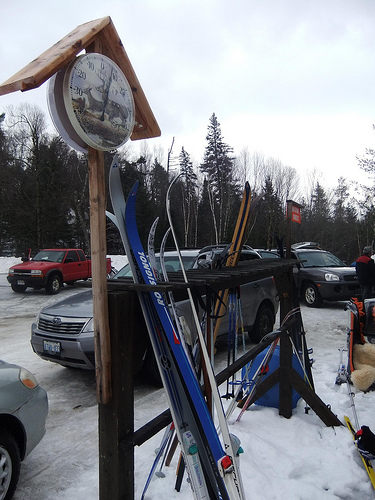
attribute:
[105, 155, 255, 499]
skis — long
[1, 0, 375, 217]
sky — white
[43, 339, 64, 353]
license plate — white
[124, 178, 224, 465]
ski — blue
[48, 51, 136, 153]
clock — round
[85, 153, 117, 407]
post — wooden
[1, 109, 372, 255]
trees — green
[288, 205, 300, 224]
sign — red